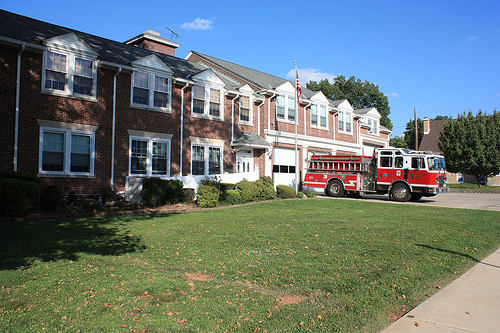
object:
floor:
[366, 133, 429, 160]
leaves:
[444, 110, 499, 180]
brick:
[33, 97, 65, 120]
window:
[37, 118, 96, 178]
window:
[43, 43, 98, 103]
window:
[129, 129, 170, 177]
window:
[130, 65, 172, 115]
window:
[188, 142, 221, 176]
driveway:
[315, 192, 499, 217]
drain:
[109, 73, 117, 191]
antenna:
[163, 24, 182, 41]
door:
[271, 147, 300, 193]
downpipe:
[110, 68, 117, 188]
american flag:
[294, 60, 303, 106]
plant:
[289, 59, 306, 111]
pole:
[293, 61, 299, 194]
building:
[0, 6, 391, 212]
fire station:
[0, 5, 397, 219]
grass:
[0, 193, 500, 330]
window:
[287, 164, 296, 173]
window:
[279, 164, 288, 173]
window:
[272, 165, 279, 172]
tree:
[441, 108, 498, 187]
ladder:
[308, 159, 367, 171]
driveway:
[436, 174, 495, 232]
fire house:
[0, 5, 387, 201]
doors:
[234, 147, 256, 188]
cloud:
[180, 16, 218, 36]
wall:
[100, 70, 129, 200]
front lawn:
[1, 192, 500, 333]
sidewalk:
[379, 180, 500, 331]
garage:
[268, 145, 303, 195]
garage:
[310, 148, 387, 172]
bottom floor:
[8, 142, 442, 197]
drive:
[308, 188, 484, 208]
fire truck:
[302, 148, 446, 200]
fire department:
[0, 0, 496, 330]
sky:
[172, 8, 445, 68]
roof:
[1, 9, 288, 91]